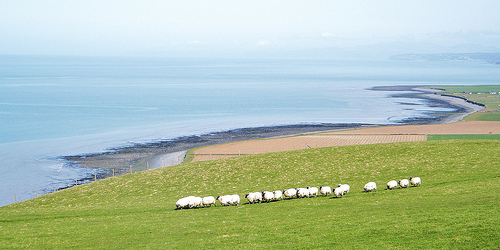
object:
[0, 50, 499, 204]
water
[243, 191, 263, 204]
sheep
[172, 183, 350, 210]
line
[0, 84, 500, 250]
grass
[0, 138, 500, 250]
field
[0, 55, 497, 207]
ocean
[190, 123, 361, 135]
shore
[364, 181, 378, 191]
sheep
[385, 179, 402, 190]
sheep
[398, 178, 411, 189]
sheep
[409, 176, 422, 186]
sheep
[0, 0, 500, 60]
sky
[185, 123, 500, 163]
strip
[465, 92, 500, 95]
pool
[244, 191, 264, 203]
animals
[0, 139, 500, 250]
land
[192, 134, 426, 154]
land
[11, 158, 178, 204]
fence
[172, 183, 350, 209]
group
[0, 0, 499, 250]
landscape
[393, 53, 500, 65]
mountains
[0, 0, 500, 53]
clouds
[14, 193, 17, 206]
poles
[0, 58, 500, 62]
horizon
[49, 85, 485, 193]
shore line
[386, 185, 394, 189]
head